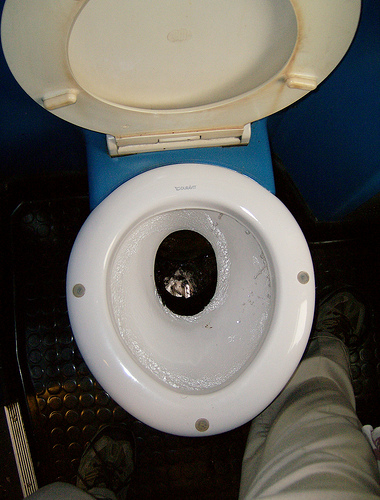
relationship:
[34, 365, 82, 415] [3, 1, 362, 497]
metal floor of bathroom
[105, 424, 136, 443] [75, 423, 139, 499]
tip of a running shoe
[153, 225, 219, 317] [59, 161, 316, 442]
black hole in a toilet bowl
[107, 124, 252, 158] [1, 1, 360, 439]
hinged base of toilet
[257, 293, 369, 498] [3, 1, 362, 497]
leg in bathroom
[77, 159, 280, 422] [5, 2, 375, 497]
toilet in a bathroom stall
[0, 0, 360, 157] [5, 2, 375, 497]
lid in a bathroom stall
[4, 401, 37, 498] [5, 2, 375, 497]
door hinge in a bathroom stall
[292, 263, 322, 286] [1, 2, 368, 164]
spot on a toilet seat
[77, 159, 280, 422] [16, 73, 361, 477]
toilet in a bathroom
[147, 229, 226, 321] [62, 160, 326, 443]
base of toilet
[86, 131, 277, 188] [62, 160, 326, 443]
support for toilet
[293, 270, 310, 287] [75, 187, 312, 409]
dots on toilet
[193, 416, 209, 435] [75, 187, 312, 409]
dots on toilet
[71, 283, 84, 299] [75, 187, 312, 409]
dots on toilet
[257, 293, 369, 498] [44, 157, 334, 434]
leg in front of toilet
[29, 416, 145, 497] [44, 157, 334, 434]
leg in front of toilet